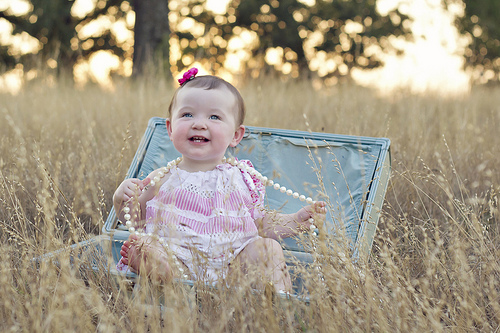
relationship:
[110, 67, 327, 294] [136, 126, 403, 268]
baby sitting in suitcase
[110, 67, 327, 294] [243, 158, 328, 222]
baby wearing pearls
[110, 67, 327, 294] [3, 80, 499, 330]
baby sitting in field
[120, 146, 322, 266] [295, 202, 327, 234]
pearl held in hand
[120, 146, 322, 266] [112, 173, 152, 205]
pearl held in hand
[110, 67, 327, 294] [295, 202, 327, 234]
baby has hand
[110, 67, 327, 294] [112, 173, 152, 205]
baby has hand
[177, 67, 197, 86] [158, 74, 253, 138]
bow in hair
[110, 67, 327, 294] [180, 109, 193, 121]
baby has eye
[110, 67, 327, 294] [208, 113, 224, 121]
baby has blue eye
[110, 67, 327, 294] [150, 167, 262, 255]
baby wearing dress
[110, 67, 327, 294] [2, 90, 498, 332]
baby showing though wheat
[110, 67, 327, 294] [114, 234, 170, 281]
baby has foot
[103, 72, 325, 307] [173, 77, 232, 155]
child has face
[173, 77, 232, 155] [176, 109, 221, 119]
face has eyes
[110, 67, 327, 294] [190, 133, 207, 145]
baby has teeth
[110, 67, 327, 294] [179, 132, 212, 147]
baby has smile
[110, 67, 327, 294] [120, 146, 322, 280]
baby playing with pearl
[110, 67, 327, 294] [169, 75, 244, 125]
baby has something in hair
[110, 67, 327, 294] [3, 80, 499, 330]
baby in field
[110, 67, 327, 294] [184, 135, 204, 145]
baby showing teeth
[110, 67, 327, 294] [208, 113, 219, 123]
baby has blue eye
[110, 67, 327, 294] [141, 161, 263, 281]
baby wearing pink clothing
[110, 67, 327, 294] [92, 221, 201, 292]
baby has toes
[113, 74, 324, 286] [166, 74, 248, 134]
baby has hair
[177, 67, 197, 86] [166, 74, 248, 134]
bow in hair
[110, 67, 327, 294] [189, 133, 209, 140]
baby has teeth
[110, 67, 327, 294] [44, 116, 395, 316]
baby sitting in suitcase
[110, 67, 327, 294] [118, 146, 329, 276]
baby holding necklace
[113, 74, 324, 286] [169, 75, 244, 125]
baby has hair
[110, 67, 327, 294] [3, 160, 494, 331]
baby sitting in yellow straw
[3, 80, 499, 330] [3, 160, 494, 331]
field has yellow straw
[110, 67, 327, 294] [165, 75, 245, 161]
baby has head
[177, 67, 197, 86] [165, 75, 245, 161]
bow on top of head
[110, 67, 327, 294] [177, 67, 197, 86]
baby wearing bow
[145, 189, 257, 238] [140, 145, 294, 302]
pattern on dress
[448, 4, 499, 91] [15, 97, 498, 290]
tree behind field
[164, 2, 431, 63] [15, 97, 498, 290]
foliage behind field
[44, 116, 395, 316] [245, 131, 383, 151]
suitcase has edge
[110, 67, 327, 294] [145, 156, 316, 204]
baby wearing pearls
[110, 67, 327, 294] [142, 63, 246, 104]
baby wearing bow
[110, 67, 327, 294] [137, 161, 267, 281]
baby wearing pink clothing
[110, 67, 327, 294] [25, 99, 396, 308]
baby sitting in suitcase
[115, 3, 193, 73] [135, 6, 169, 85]
tree has bark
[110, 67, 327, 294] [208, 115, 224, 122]
baby has eye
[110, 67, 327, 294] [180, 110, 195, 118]
baby has blue eye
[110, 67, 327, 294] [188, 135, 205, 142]
baby has teeth